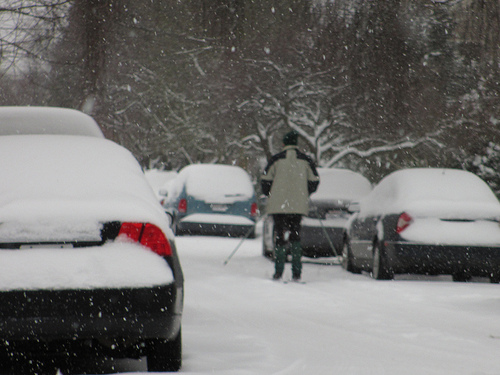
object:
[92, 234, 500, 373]
snow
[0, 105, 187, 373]
car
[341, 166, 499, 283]
car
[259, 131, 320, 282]
person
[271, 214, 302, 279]
pants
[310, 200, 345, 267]
pole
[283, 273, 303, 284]
snow shoes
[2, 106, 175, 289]
snow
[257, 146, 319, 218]
coat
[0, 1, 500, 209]
trees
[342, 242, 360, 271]
tire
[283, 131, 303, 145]
hat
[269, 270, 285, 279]
shoes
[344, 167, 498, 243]
snow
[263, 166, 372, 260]
car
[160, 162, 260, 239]
car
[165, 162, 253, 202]
snow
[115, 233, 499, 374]
ground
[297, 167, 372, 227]
snow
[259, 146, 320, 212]
top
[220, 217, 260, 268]
ski poles